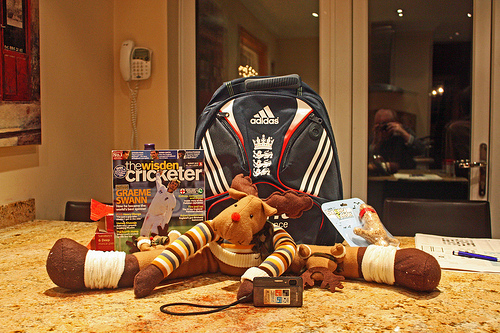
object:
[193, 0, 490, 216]
window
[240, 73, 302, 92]
handle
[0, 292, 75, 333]
table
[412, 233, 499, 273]
paper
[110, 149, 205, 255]
book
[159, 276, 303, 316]
camera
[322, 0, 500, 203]
door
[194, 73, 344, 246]
backpack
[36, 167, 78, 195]
floor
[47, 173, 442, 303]
animal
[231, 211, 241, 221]
nose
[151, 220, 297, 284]
shirt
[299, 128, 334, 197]
lines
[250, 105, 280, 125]
logo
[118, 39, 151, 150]
phone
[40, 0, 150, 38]
wall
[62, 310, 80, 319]
counter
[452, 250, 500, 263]
pen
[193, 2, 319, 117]
reflection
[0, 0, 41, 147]
art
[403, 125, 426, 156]
arm